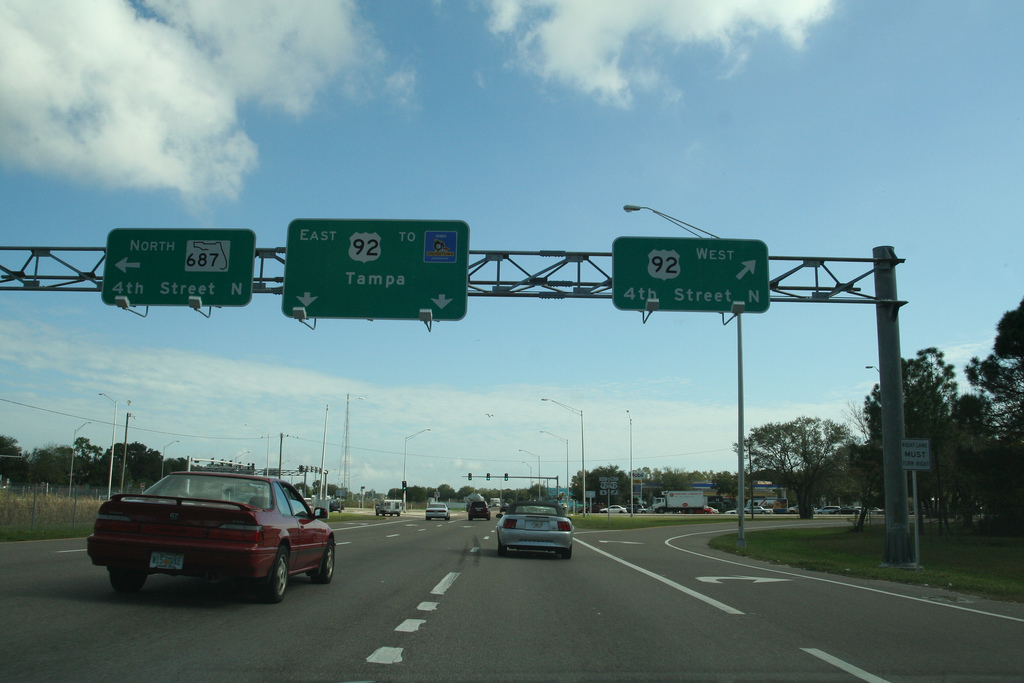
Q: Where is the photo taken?
A: On the I4 highway.